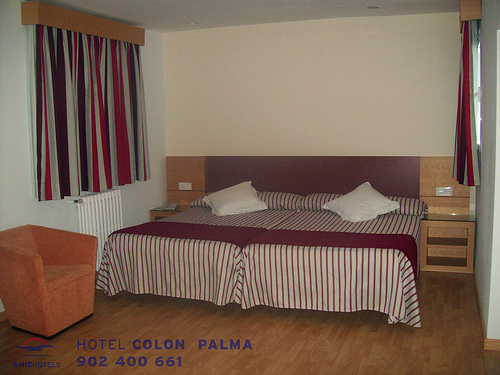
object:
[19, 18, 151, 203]
curtains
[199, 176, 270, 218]
pillow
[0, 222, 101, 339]
chair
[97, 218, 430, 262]
blanket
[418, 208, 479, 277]
table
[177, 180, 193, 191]
receptor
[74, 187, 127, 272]
radiator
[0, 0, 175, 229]
wall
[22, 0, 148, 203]
window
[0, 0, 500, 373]
bedroom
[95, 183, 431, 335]
sheets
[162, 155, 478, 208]
headboard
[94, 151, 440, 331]
bed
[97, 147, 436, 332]
bedspread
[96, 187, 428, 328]
stripes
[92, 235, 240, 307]
bottom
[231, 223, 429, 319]
bottom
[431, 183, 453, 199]
outlet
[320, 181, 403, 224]
pillow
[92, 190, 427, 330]
comforter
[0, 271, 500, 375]
floors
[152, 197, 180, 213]
phone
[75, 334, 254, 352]
name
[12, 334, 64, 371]
logo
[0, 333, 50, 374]
corner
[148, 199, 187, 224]
nightstand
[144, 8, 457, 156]
wall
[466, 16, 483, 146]
light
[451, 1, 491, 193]
window